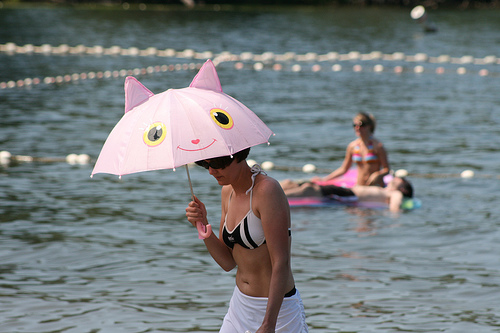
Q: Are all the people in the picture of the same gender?
A: No, they are both male and female.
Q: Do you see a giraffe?
A: No, there are no giraffes.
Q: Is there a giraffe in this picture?
A: No, there are no giraffes.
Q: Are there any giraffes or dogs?
A: No, there are no giraffes or dogs.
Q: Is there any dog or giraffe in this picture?
A: No, there are no giraffes or dogs.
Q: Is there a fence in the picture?
A: No, there are no fences.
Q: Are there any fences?
A: No, there are no fences.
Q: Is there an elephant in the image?
A: No, there are no elephants.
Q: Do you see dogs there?
A: No, there are no dogs.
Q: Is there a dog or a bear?
A: No, there are no dogs or bears.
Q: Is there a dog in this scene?
A: No, there are no dogs.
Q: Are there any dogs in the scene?
A: No, there are no dogs.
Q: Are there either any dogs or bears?
A: No, there are no dogs or bears.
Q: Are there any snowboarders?
A: No, there are no snowboarders.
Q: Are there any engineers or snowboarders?
A: No, there are no snowboarders or engineers.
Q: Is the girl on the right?
A: Yes, the girl is on the right of the image.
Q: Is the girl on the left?
A: No, the girl is on the right of the image.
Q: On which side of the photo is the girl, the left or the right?
A: The girl is on the right of the image.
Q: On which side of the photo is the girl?
A: The girl is on the right of the image.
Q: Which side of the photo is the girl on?
A: The girl is on the right of the image.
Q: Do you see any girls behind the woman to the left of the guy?
A: Yes, there is a girl behind the woman.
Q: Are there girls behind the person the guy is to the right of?
A: Yes, there is a girl behind the woman.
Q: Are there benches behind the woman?
A: No, there is a girl behind the woman.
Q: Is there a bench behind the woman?
A: No, there is a girl behind the woman.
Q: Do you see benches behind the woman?
A: No, there is a girl behind the woman.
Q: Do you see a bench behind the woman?
A: No, there is a girl behind the woman.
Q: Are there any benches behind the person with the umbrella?
A: No, there is a girl behind the woman.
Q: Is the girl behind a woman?
A: Yes, the girl is behind a woman.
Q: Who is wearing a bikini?
A: The girl is wearing a bikini.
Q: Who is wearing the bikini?
A: The girl is wearing a bikini.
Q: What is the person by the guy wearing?
A: The girl is wearing a bikini.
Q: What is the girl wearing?
A: The girl is wearing a bikini.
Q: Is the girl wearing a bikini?
A: Yes, the girl is wearing a bikini.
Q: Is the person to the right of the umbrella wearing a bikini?
A: Yes, the girl is wearing a bikini.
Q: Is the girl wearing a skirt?
A: No, the girl is wearing a bikini.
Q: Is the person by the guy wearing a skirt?
A: No, the girl is wearing a bikini.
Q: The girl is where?
A: The girl is in the water.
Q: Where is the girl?
A: The girl is in the water.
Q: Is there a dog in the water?
A: No, there is a girl in the water.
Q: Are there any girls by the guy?
A: Yes, there is a girl by the guy.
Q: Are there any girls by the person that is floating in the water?
A: Yes, there is a girl by the guy.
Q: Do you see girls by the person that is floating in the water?
A: Yes, there is a girl by the guy.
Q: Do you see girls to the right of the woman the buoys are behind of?
A: Yes, there is a girl to the right of the woman.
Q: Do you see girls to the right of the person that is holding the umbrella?
A: Yes, there is a girl to the right of the woman.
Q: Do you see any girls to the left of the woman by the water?
A: No, the girl is to the right of the woman.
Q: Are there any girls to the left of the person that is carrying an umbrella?
A: No, the girl is to the right of the woman.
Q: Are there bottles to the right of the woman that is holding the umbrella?
A: No, there is a girl to the right of the woman.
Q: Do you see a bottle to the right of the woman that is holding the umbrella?
A: No, there is a girl to the right of the woman.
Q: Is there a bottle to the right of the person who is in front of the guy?
A: No, there is a girl to the right of the woman.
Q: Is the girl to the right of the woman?
A: Yes, the girl is to the right of the woman.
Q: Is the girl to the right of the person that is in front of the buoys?
A: Yes, the girl is to the right of the woman.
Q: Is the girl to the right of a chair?
A: No, the girl is to the right of the woman.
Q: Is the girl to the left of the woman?
A: No, the girl is to the right of the woman.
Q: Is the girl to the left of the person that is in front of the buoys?
A: No, the girl is to the right of the woman.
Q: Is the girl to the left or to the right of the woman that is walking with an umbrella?
A: The girl is to the right of the woman.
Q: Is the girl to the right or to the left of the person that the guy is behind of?
A: The girl is to the right of the woman.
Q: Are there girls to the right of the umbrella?
A: Yes, there is a girl to the right of the umbrella.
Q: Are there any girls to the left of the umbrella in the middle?
A: No, the girl is to the right of the umbrella.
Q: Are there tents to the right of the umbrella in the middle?
A: No, there is a girl to the right of the umbrella.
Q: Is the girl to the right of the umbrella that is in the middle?
A: Yes, the girl is to the right of the umbrella.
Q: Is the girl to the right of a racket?
A: No, the girl is to the right of the umbrella.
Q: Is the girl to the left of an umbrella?
A: No, the girl is to the right of an umbrella.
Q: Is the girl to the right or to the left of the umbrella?
A: The girl is to the right of the umbrella.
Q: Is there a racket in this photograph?
A: No, there are no rackets.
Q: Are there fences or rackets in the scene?
A: No, there are no rackets or fences.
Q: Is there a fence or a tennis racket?
A: No, there are no rackets or fences.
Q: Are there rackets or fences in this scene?
A: No, there are no rackets or fences.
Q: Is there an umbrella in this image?
A: Yes, there is an umbrella.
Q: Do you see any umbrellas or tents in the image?
A: Yes, there is an umbrella.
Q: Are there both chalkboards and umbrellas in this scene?
A: No, there is an umbrella but no chalkboards.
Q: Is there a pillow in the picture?
A: No, there are no pillows.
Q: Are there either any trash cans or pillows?
A: No, there are no pillows or trash cans.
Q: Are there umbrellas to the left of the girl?
A: Yes, there is an umbrella to the left of the girl.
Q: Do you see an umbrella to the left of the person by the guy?
A: Yes, there is an umbrella to the left of the girl.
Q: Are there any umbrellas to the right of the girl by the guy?
A: No, the umbrella is to the left of the girl.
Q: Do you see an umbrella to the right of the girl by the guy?
A: No, the umbrella is to the left of the girl.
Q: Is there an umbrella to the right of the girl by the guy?
A: No, the umbrella is to the left of the girl.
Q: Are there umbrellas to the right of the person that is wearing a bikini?
A: No, the umbrella is to the left of the girl.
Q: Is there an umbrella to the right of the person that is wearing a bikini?
A: No, the umbrella is to the left of the girl.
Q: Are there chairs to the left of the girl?
A: No, there is an umbrella to the left of the girl.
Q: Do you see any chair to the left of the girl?
A: No, there is an umbrella to the left of the girl.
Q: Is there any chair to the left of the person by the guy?
A: No, there is an umbrella to the left of the girl.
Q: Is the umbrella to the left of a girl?
A: Yes, the umbrella is to the left of a girl.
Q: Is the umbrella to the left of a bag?
A: No, the umbrella is to the left of a girl.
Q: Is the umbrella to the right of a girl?
A: No, the umbrella is to the left of a girl.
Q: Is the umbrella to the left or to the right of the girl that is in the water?
A: The umbrella is to the left of the girl.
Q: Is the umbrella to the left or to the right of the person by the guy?
A: The umbrella is to the left of the girl.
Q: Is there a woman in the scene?
A: Yes, there is a woman.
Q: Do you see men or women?
A: Yes, there is a woman.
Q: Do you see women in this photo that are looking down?
A: Yes, there is a woman that is looking down.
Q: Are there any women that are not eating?
A: Yes, there is a woman that is looking down.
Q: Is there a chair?
A: No, there are no chairs.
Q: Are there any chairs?
A: No, there are no chairs.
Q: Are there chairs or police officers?
A: No, there are no chairs or police officers.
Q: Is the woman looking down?
A: Yes, the woman is looking down.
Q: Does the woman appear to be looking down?
A: Yes, the woman is looking down.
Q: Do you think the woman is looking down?
A: Yes, the woman is looking down.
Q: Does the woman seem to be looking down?
A: Yes, the woman is looking down.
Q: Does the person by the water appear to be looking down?
A: Yes, the woman is looking down.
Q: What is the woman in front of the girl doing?
A: The woman is looking down.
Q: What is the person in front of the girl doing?
A: The woman is looking down.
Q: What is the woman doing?
A: The woman is looking down.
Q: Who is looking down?
A: The woman is looking down.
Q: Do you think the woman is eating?
A: No, the woman is looking down.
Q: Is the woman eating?
A: No, the woman is looking down.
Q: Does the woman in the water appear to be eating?
A: No, the woman is looking down.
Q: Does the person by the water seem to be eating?
A: No, the woman is looking down.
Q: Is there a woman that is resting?
A: No, there is a woman but she is looking down.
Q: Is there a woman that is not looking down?
A: No, there is a woman but she is looking down.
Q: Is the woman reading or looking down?
A: The woman is looking down.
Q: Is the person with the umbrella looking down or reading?
A: The woman is looking down.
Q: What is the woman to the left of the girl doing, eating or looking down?
A: The woman is looking down.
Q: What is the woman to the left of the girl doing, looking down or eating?
A: The woman is looking down.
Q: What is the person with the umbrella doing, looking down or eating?
A: The woman is looking down.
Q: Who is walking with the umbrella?
A: The woman is walking with the umbrella.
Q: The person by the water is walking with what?
A: The woman is walking with an umbrella.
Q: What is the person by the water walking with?
A: The woman is walking with an umbrella.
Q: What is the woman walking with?
A: The woman is walking with an umbrella.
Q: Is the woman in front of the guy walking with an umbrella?
A: Yes, the woman is walking with an umbrella.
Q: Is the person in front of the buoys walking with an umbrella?
A: Yes, the woman is walking with an umbrella.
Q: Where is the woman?
A: The woman is in the water.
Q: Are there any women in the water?
A: Yes, there is a woman in the water.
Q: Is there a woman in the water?
A: Yes, there is a woman in the water.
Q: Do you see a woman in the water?
A: Yes, there is a woman in the water.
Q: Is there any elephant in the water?
A: No, there is a woman in the water.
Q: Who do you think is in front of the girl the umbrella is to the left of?
A: The woman is in front of the girl.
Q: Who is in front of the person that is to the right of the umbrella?
A: The woman is in front of the girl.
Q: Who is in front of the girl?
A: The woman is in front of the girl.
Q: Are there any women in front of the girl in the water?
A: Yes, there is a woman in front of the girl.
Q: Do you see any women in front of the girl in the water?
A: Yes, there is a woman in front of the girl.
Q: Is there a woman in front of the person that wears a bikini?
A: Yes, there is a woman in front of the girl.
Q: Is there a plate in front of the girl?
A: No, there is a woman in front of the girl.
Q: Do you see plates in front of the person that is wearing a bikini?
A: No, there is a woman in front of the girl.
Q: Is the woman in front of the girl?
A: Yes, the woman is in front of the girl.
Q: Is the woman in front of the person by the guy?
A: Yes, the woman is in front of the girl.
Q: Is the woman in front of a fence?
A: No, the woman is in front of the girl.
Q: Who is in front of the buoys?
A: The woman is in front of the buoys.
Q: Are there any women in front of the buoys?
A: Yes, there is a woman in front of the buoys.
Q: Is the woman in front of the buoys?
A: Yes, the woman is in front of the buoys.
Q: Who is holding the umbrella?
A: The woman is holding the umbrella.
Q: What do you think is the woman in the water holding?
A: The woman is holding the umbrella.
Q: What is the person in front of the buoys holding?
A: The woman is holding the umbrella.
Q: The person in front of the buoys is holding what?
A: The woman is holding the umbrella.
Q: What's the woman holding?
A: The woman is holding the umbrella.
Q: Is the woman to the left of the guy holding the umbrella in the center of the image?
A: Yes, the woman is holding the umbrella.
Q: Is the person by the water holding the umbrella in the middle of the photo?
A: Yes, the woman is holding the umbrella.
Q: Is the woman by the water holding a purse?
A: No, the woman is holding the umbrella.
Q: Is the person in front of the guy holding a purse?
A: No, the woman is holding the umbrella.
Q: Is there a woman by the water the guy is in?
A: Yes, there is a woman by the water.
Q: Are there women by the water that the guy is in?
A: Yes, there is a woman by the water.